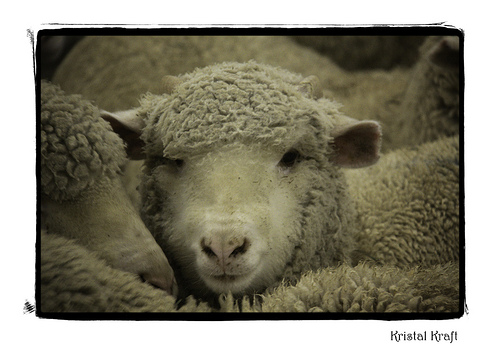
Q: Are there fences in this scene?
A: No, there are no fences.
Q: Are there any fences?
A: No, there are no fences.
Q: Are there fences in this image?
A: No, there are no fences.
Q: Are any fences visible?
A: No, there are no fences.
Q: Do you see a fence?
A: No, there are no fences.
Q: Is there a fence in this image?
A: No, there are no fences.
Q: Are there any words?
A: Yes, there are words.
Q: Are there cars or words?
A: Yes, there are words.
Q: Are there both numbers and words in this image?
A: No, there are words but no numbers.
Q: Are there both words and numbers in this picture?
A: No, there are words but no numbers.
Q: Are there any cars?
A: No, there are no cars.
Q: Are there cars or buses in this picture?
A: No, there are no cars or buses.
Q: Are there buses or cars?
A: No, there are no cars or buses.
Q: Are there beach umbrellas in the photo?
A: No, there are no beach umbrellas.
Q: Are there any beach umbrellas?
A: No, there are no beach umbrellas.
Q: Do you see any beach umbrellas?
A: No, there are no beach umbrellas.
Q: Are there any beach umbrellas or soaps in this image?
A: No, there are no beach umbrellas or soaps.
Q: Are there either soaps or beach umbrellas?
A: No, there are no beach umbrellas or soaps.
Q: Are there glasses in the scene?
A: No, there are no glasses.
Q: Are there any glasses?
A: No, there are no glasses.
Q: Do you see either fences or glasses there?
A: No, there are no glasses or fences.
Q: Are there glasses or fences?
A: No, there are no glasses or fences.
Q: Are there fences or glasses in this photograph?
A: No, there are no glasses or fences.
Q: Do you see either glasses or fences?
A: No, there are no glasses or fences.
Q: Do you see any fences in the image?
A: No, there are no fences.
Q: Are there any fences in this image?
A: No, there are no fences.